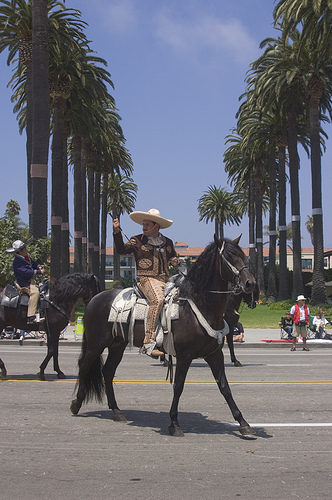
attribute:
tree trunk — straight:
[100, 169, 108, 291]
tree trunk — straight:
[93, 167, 101, 277]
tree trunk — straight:
[71, 130, 83, 271]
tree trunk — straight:
[60, 117, 69, 276]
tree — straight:
[20, 7, 51, 236]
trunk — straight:
[305, 2, 326, 293]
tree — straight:
[273, 37, 292, 266]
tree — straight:
[251, 111, 266, 304]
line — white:
[256, 417, 328, 427]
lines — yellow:
[3, 378, 331, 387]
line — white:
[231, 419, 329, 427]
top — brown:
[142, 236, 173, 281]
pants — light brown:
[133, 276, 183, 362]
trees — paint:
[41, 209, 100, 253]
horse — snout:
[245, 277, 260, 294]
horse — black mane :
[57, 229, 279, 440]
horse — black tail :
[72, 321, 105, 404]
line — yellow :
[6, 373, 331, 387]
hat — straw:
[131, 207, 172, 230]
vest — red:
[292, 301, 310, 325]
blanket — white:
[110, 281, 183, 325]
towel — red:
[262, 338, 297, 344]